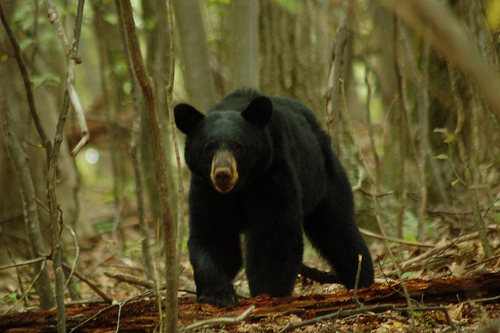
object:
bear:
[173, 87, 376, 310]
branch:
[35, 200, 115, 263]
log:
[3, 268, 498, 325]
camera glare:
[77, 143, 113, 175]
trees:
[8, 0, 175, 315]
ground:
[386, 237, 469, 333]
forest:
[3, 0, 499, 331]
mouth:
[211, 173, 240, 194]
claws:
[192, 287, 241, 313]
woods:
[4, 3, 498, 329]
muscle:
[212, 84, 278, 108]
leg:
[303, 216, 376, 281]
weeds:
[0, 210, 182, 332]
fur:
[265, 122, 321, 150]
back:
[224, 91, 305, 117]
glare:
[79, 134, 106, 169]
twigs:
[70, 255, 487, 323]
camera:
[2, 2, 500, 333]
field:
[4, 0, 496, 328]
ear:
[241, 98, 279, 122]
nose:
[205, 153, 237, 183]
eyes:
[203, 145, 242, 155]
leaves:
[79, 211, 137, 264]